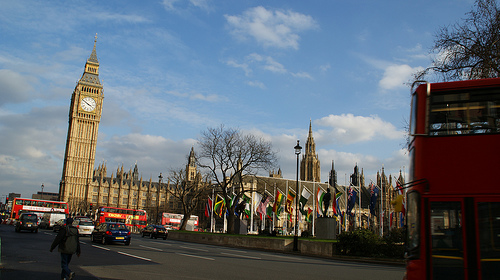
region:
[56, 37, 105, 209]
a tall clock tower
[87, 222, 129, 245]
a black car on road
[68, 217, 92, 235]
a silver car on road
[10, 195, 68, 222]
a red double decker bus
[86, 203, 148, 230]
a red double decker bus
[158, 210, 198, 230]
a red double decker bus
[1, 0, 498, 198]
a cloudy blue sky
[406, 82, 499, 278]
a red double decker bus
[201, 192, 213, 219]
a waving flag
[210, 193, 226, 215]
a waving flag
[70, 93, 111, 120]
clock on the tower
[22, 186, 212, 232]
thre red buses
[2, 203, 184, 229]
buses are double deckers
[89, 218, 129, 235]
blue car behind the other car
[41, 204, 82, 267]
person walking on the sidewalk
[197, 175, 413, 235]
flags along the sidewalk wall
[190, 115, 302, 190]
tree does not have leaves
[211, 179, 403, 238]
flags are on poles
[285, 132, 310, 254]
light pole in front of the flags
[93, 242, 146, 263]
white lines in the street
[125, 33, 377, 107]
this is the sky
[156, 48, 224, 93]
the sky is blue in color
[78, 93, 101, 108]
this is a clock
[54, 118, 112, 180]
this is a building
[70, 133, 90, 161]
the wall is brown in color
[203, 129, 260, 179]
this is a tree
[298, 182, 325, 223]
this is a flag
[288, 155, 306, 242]
this is a pole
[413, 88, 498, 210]
this is a bus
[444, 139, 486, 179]
the bus is red in color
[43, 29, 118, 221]
the Big Ben clock in London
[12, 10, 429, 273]
the city of London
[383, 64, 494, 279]
a London city bus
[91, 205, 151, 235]
a double decker bus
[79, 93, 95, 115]
the clock on Big Ben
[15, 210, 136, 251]
several cars driving down the street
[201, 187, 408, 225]
a long line of different flags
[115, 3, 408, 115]
a few clouds in the sky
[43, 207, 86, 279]
a man walking down the street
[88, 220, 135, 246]
a blue car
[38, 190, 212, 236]
three red buses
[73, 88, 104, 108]
clock on the tower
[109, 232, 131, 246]
license plate on the car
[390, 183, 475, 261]
bus driving on the road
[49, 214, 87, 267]
person walking on side of road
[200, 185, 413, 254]
flags flying on ledge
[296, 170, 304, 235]
flag poles are white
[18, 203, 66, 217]
buses are double deckers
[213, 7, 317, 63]
white puffy clouds in the sky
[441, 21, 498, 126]
tree on the side of bus